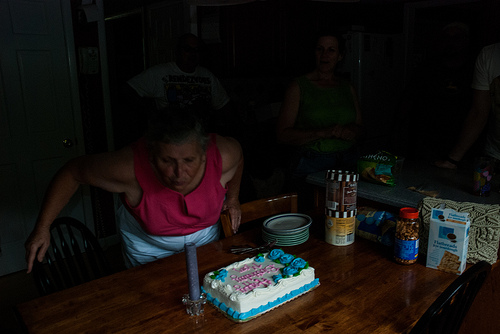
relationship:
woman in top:
[88, 124, 260, 244] [128, 166, 279, 243]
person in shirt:
[98, 114, 283, 259] [112, 153, 232, 240]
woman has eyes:
[49, 82, 276, 286] [151, 143, 208, 175]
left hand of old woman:
[218, 194, 243, 232] [19, 110, 258, 273]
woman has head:
[15, 117, 253, 277] [145, 107, 205, 194]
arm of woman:
[213, 145, 248, 230] [24, 112, 268, 264]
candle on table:
[181, 240, 206, 300] [1, 211, 486, 332]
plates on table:
[261, 210, 314, 249] [13, 197, 498, 330]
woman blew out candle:
[133, 122, 221, 210] [181, 234, 204, 306]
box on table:
[424, 205, 474, 280] [13, 197, 498, 330]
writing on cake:
[227, 254, 286, 296] [226, 265, 291, 287]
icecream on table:
[322, 159, 365, 252] [1, 211, 486, 332]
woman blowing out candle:
[104, 141, 285, 273] [152, 231, 236, 313]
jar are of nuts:
[393, 197, 425, 274] [400, 222, 419, 241]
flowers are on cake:
[264, 245, 308, 275] [194, 250, 324, 323]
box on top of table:
[421, 198, 477, 279] [13, 180, 469, 331]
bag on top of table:
[361, 147, 404, 185] [0, 193, 460, 332]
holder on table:
[180, 290, 210, 326] [1, 211, 486, 332]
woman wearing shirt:
[28, 115, 246, 271] [124, 139, 225, 236]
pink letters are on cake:
[231, 258, 282, 292] [196, 247, 325, 317]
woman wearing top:
[99, 130, 353, 317] [289, 69, 369, 189]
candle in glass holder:
[182, 243, 207, 315] [182, 293, 209, 320]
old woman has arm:
[25, 119, 246, 272] [23, 146, 130, 273]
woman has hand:
[26, 122, 244, 253] [25, 234, 61, 274]